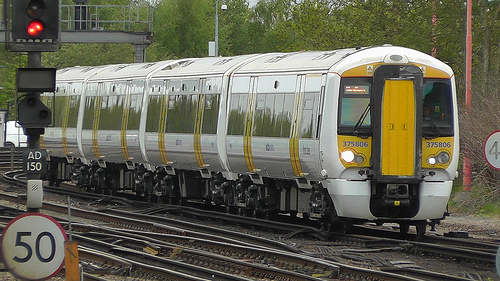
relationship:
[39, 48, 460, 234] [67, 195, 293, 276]
train on tracks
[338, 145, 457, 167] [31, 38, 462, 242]
lights on train